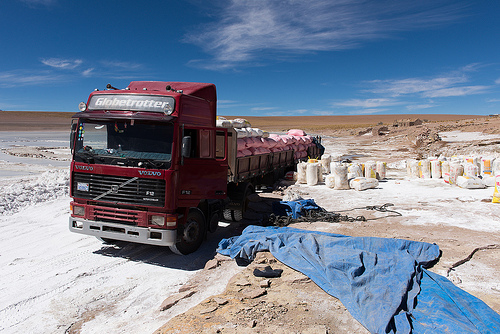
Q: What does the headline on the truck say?
A: Globetrotter.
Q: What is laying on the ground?
A: Tarp.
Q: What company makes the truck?
A: Volvo.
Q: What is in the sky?
A: Clouds.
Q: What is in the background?
A: Desert.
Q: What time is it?
A: Afternoon.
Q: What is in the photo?
A: A truck.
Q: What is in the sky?
A: Clouds.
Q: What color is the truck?
A: Red.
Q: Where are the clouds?
A: In the sky.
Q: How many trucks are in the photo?
A: One.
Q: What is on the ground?
A: A blue sheet.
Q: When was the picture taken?
A: Daytime.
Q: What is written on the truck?
A: "Globetrotter".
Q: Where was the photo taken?
A: Desert.